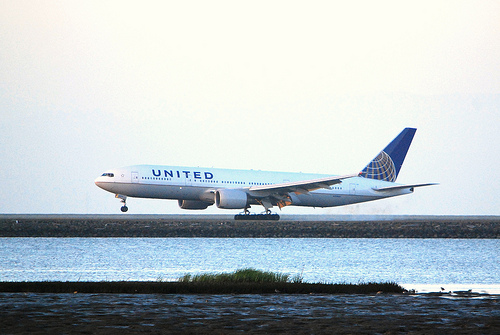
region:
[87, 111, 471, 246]
a commercial plane flying in the air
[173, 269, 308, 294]
tall green sea grass growing on the shore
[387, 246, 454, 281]
blue water rippling in the sea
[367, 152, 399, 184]
a company logo on the fin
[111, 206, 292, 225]
landing gear on the bottom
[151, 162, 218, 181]
blue letters on the body of the plane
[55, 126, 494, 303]
a plane preparing to land on water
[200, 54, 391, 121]
an overcast white sky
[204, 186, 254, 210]
a large wing engine on the plane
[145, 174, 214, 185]
passenger windows on the plane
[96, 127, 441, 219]
airplane is landing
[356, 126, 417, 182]
tail on airplane is blue and yellow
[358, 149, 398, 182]
yellow logo on tail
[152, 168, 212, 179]
blue logo on side of airplane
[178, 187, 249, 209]
two engines on airplane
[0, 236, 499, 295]
water in front of airplane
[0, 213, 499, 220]
flat runway under airplane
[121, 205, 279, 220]
wheels under airplane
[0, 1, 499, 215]
sky is clear above airplane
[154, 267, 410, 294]
grass in water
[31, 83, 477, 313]
a plane taking off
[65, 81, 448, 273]
a united commercial airliner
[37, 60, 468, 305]
plane on a runway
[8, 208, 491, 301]
runway near moving water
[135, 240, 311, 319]
tufts of grass near river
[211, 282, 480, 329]
muddy space near grass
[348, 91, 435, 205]
a bright blue plane tail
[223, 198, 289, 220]
some of the planes landing gear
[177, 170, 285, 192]
a row of windows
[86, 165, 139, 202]
the plane's cockpit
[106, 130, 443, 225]
the plane is a united airline plane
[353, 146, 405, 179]
the tail has a world picture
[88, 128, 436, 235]
the plane is landing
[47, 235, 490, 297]
there is water next to the plane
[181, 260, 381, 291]
thre is green grass in the riverbak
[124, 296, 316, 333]
the sand is muddy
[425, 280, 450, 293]
there is a bird in the sand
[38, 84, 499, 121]
the sky is not clear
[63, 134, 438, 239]
plane has two engines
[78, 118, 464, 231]
the plane is blue and white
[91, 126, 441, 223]
airplane taking off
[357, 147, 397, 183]
drawing of a vector sphere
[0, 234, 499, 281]
blue river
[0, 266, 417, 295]
low brown and green grasses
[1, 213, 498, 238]
a flat rocky landscape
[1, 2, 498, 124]
bright clear sky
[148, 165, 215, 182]
blue united logo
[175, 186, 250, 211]
white jet engines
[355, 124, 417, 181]
blue tail of an airplane with orange and white lines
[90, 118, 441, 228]
white airplane with blue and orange markings